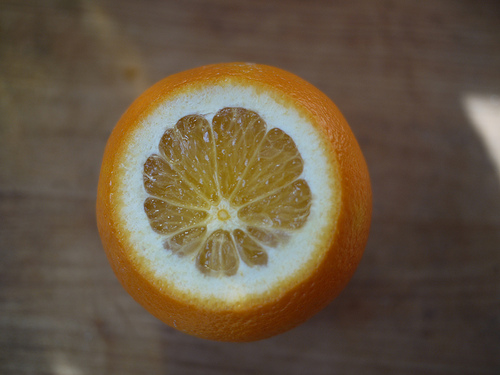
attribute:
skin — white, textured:
[181, 89, 245, 105]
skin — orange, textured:
[226, 62, 294, 89]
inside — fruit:
[133, 95, 320, 248]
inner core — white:
[203, 186, 241, 237]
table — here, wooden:
[345, 42, 446, 148]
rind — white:
[284, 232, 337, 281]